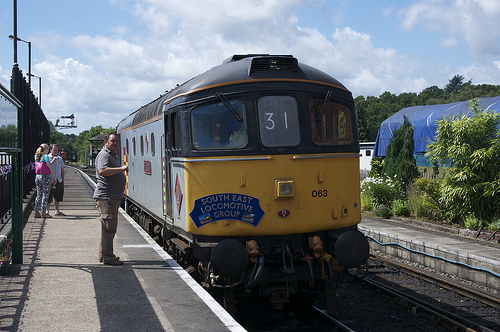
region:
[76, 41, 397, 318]
a man is standing beside the train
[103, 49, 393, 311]
the train has number 31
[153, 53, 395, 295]
the front of the train is yellow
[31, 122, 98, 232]
people are standing on the sidewalk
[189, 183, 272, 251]
the sign is blue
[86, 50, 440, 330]
a train on train tracks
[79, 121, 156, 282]
the man is wearing khaki pants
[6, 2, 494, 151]
the sky has clouds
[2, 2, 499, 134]
the sky is blue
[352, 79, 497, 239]
the trees are green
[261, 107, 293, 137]
the number 31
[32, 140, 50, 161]
a woman with a ponytail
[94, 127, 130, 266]
a man wearing a grey shirt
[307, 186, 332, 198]
the number 63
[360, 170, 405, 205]
white and green plants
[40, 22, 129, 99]
clouds in the sky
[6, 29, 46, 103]
street lights can be seen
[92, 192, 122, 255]
tan cargo pants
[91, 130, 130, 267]
a man wearing tan cargo pants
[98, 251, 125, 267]
brown shoe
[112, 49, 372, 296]
Train with the number 31 on front.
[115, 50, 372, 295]
Yellow, black and silver train.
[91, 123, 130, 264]
Man standing on the platform.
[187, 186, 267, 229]
Placard on train that says South East Locomotive Group.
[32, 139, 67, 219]
Man and woman talking.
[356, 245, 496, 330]
Train tracks.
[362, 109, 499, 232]
Foliage near the platform.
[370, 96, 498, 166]
Structure covered in blue tarp.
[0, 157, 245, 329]
Platform where train stops.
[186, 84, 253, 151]
Front window of the train.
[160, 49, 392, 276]
front of a yellow train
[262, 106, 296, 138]
number 31 on a train window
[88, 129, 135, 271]
male on train platform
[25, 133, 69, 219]
people waiting on train platform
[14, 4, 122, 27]
blue sky in the distance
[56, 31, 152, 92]
white clouds in the sky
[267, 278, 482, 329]
train tracks on the ground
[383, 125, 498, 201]
green foliage on trees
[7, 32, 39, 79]
light on a metal pole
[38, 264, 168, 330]
shadow casted on the ground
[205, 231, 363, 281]
Front Bumper of the Train.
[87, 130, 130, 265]
An Adult White Man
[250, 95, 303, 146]
The Number 31 on the front of the train.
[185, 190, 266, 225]
"South East Locomotive Group" Sensor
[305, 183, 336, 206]
The 063 Number on the front of the train.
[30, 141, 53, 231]
A Blonde Teenage Girl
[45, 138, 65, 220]
An Older White Man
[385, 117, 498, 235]
A group of shrubberies.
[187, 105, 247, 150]
Right Train Window.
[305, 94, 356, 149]
Left Train Window